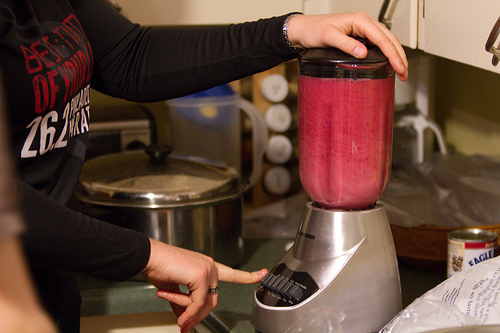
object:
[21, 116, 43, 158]
white lettering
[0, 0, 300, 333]
shirt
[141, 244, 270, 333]
hand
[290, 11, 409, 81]
hand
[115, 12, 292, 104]
arm